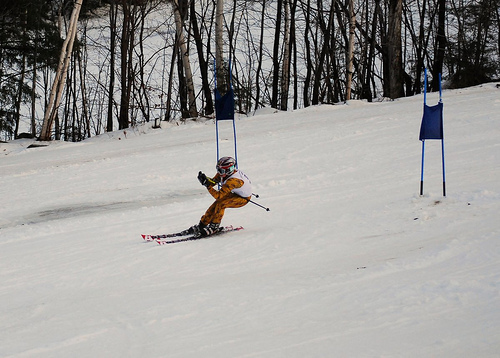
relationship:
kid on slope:
[184, 154, 254, 238] [3, 79, 499, 357]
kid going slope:
[184, 154, 254, 238] [3, 79, 499, 357]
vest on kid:
[220, 169, 255, 198] [184, 154, 254, 238]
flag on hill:
[419, 68, 449, 201] [3, 79, 499, 357]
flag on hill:
[211, 57, 239, 163] [3, 79, 499, 357]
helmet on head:
[214, 156, 238, 167] [216, 156, 237, 176]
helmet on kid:
[214, 156, 238, 167] [184, 154, 254, 238]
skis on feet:
[141, 223, 247, 247] [183, 222, 222, 237]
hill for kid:
[3, 79, 499, 357] [184, 154, 254, 238]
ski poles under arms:
[203, 172, 272, 213] [200, 173, 241, 203]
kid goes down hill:
[184, 154, 254, 238] [3, 79, 499, 357]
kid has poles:
[184, 154, 254, 238] [203, 172, 272, 213]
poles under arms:
[203, 172, 272, 213] [200, 173, 241, 203]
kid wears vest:
[184, 154, 257, 239] [220, 169, 255, 198]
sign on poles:
[419, 68, 449, 201] [417, 138, 450, 201]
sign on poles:
[211, 57, 239, 163] [214, 121, 240, 161]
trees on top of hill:
[3, 1, 496, 146] [3, 79, 499, 357]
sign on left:
[211, 57, 239, 163] [211, 58, 240, 160]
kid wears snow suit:
[184, 154, 254, 238] [197, 171, 250, 234]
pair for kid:
[203, 172, 272, 213] [184, 154, 254, 238]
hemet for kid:
[214, 156, 238, 167] [184, 154, 254, 238]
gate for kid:
[208, 67, 451, 203] [184, 154, 254, 238]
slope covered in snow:
[3, 79, 499, 357] [2, 83, 499, 358]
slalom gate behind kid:
[208, 67, 451, 203] [184, 154, 254, 238]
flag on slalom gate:
[419, 68, 449, 201] [208, 67, 451, 203]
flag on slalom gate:
[211, 57, 239, 163] [208, 67, 451, 203]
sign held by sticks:
[212, 87, 237, 121] [214, 121, 240, 161]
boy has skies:
[184, 154, 257, 239] [141, 223, 247, 247]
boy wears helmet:
[184, 154, 257, 239] [214, 156, 238, 167]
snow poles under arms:
[203, 172, 272, 213] [200, 173, 241, 203]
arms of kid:
[200, 173, 241, 203] [184, 154, 254, 238]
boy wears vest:
[184, 154, 257, 239] [220, 169, 255, 198]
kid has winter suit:
[184, 154, 254, 238] [197, 171, 250, 234]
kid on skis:
[184, 154, 254, 238] [141, 223, 247, 247]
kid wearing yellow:
[184, 154, 254, 238] [197, 171, 250, 234]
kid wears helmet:
[184, 154, 254, 238] [214, 156, 238, 167]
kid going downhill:
[184, 154, 254, 238] [3, 79, 499, 357]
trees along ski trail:
[3, 1, 496, 146] [3, 79, 499, 357]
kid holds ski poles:
[184, 154, 254, 238] [203, 172, 272, 213]